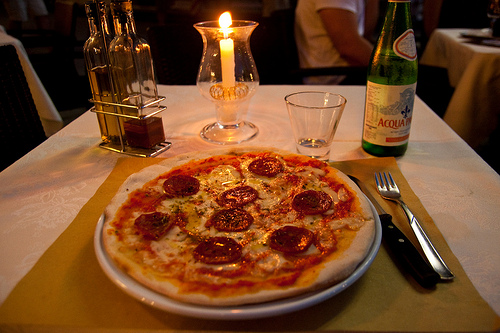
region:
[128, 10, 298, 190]
candle is so bright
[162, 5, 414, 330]
candle is so bright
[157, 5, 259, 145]
candle is so bright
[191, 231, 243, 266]
red pepperoni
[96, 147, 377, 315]
pepperoni and cheese pizza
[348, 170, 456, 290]
silver fork and knife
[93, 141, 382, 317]
small pizza on a white plate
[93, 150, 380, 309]
small pizza with 8 pepperonis on it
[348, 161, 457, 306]
silver utensils on a mat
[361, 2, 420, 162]
green glass bottle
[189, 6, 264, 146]
candle in a glass container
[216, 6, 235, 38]
bright burning flame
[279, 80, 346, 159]
clear empty glass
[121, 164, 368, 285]
Medium sized pepperoni pizza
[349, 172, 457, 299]
Fork and knife beside plate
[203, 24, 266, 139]
Candle in glass casing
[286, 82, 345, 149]
Empty drinking glass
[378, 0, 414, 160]
Green bottle of water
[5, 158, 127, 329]
Edge of yellow placemat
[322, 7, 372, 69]
Arm of person in background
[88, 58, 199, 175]
Oil and vinegar in glass containers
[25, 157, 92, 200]
Portion of white tablecloth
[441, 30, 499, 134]
Another table nearby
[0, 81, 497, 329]
a white tablecloth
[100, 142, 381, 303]
a pizza on a plate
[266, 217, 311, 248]
a pepperoni on a pizza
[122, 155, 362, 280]
cheese on a pizza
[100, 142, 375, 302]
a white pizza crust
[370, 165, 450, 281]
a fork on a placemat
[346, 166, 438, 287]
a knife next to a plate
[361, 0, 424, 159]
a green bottle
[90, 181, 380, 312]
a round white plate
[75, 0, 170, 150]
oil and vinegar bottles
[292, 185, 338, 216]
pepperoni baked until crispy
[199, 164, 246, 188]
melted mozzerella cheese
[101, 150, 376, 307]
one round cooked pizza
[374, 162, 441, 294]
stainless steel fork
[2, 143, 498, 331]
a gold colored placemat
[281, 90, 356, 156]
a smalled sized glass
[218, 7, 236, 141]
a lighted white candle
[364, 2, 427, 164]
green bottle of wine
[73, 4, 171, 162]
oil and vinegar carafe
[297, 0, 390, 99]
a person sitting at another table